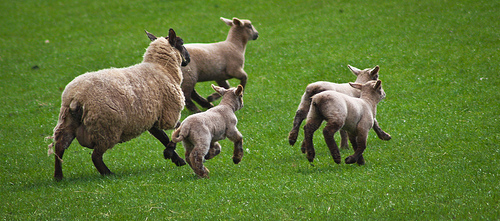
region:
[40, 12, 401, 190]
Herd of sheep on the grass.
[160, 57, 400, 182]
Baby sheep in the herd.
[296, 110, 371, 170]
black legs on the sheep.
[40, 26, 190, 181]
Adult lamb in the herd.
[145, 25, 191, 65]
black face on the herd.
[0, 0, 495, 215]
Green grass covering the ground.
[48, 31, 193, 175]
Wool covering the seep.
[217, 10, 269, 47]
White face on the lamb.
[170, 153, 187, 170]
Black hoof on the sheep.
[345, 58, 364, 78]
White ear on the baby sheep.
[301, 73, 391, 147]
brown sheep in green field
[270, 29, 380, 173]
brown sheep in green field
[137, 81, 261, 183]
brown sheep in green field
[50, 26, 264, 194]
brown sheep in green field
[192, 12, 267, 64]
brown sheep in green field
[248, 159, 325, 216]
short green and yellow grass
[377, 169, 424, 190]
short green and yellow grass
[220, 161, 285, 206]
short green and yellow grass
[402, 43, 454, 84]
short green and yellow grass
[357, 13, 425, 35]
short green and yellow grass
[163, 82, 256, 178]
young sheep near adult sheep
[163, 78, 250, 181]
young sheep running on grass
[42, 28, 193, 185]
adult sheep running on grass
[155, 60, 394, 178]
three young sheep running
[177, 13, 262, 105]
sheep with ears back running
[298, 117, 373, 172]
black legs of young sheep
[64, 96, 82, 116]
sheep tail on adult sheep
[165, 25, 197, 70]
side of adult sheep face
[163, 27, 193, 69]
black face of adult sheep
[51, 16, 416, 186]
this is a group of animals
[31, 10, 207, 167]
this is a sheep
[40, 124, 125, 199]
back legs of sheep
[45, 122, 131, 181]
black legs of sheep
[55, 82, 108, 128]
tail on the sheep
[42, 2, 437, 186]
animals running in field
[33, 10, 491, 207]
the field is green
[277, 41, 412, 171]
two small animals together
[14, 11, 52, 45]
short green and yellow grass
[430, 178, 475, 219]
short green and yellow grass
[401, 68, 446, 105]
short green and yellow grass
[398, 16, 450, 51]
short green and yellow grass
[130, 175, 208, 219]
short green and yellow grass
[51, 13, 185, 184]
brown sheep in field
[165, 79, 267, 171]
brown sheep in field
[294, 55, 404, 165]
brown sheep in field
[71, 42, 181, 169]
the sheep is wooly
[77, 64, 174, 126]
the wool is tan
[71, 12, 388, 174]
the sheep are running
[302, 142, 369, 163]
the hooves are black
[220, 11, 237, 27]
the ears are pointed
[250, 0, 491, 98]
the grass is cut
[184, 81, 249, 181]
the small sheep is trotting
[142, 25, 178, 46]
the ears are black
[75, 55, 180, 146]
the coat is thick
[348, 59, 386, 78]
sheep has ears on top of head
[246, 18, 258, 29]
sheep has eye on side of head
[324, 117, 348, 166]
sheep has a leg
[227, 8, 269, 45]
sheep has a head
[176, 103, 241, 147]
sheep has a torso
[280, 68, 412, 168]
sheep running on the grass